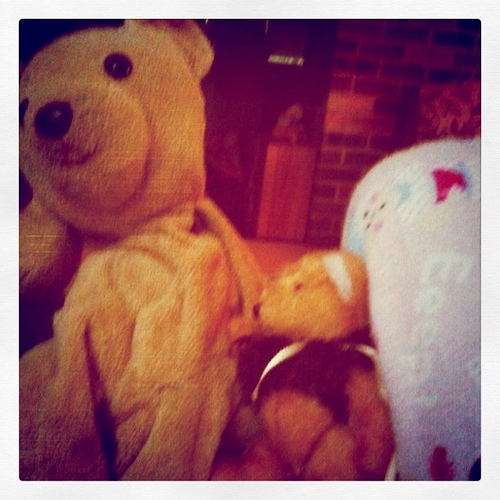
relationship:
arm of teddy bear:
[130, 237, 229, 392] [20, 22, 261, 481]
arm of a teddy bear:
[130, 237, 229, 392] [20, 22, 261, 481]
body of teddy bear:
[61, 239, 240, 481] [20, 22, 261, 481]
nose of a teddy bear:
[34, 102, 74, 140] [20, 22, 261, 481]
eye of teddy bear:
[105, 52, 135, 80] [20, 22, 261, 481]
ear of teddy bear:
[124, 19, 215, 86] [20, 22, 261, 481]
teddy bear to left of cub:
[20, 22, 261, 481] [240, 250, 395, 482]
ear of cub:
[324, 250, 367, 303] [240, 250, 395, 482]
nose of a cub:
[251, 303, 264, 317] [240, 250, 395, 482]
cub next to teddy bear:
[240, 250, 395, 482] [20, 22, 261, 481]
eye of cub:
[292, 283, 305, 291] [240, 250, 395, 482]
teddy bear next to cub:
[20, 22, 261, 481] [240, 250, 395, 482]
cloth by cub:
[343, 138, 478, 481] [240, 250, 395, 482]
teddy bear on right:
[20, 22, 261, 481] [22, 22, 69, 243]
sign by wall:
[264, 28, 310, 67] [304, 20, 482, 247]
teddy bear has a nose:
[20, 22, 261, 481] [34, 102, 74, 140]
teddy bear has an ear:
[20, 22, 261, 481] [124, 19, 215, 86]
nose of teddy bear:
[34, 102, 74, 140] [20, 22, 261, 481]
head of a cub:
[253, 251, 369, 343] [240, 250, 395, 482]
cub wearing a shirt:
[240, 250, 395, 482] [248, 336, 383, 423]